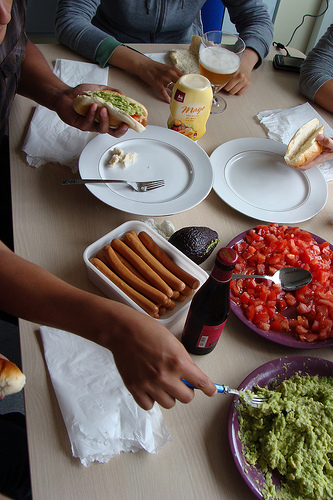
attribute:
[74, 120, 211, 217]
plate — white, round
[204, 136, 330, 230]
plate — white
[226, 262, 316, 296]
spoon — grey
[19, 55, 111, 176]
paper — white, folded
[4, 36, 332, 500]
table — cream, wood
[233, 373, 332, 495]
food — green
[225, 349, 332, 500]
plate — purple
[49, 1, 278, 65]
blouse — grey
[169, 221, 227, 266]
avocado — cut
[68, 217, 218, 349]
dish — rectangular, white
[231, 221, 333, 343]
tomato — small, pieces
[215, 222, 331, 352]
plate — purple, round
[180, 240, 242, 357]
bottle — dark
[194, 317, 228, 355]
label — red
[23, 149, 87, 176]
edge — jagged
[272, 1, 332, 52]
cable — black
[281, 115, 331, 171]
bun — empty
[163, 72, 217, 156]
jar — mayonnaise